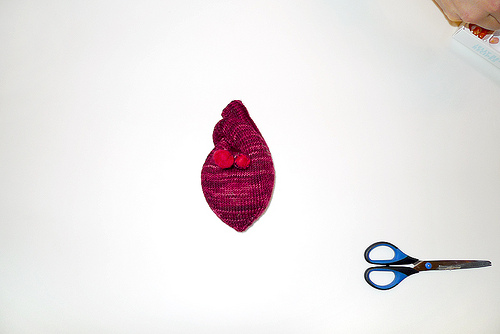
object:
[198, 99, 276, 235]
cloth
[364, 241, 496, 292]
scissors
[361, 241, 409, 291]
handle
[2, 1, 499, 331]
table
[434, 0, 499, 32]
hand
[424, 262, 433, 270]
screw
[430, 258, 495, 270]
long part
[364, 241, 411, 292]
outline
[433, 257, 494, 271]
blade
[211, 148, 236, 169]
ball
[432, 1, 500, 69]
corner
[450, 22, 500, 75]
something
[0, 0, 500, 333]
photo